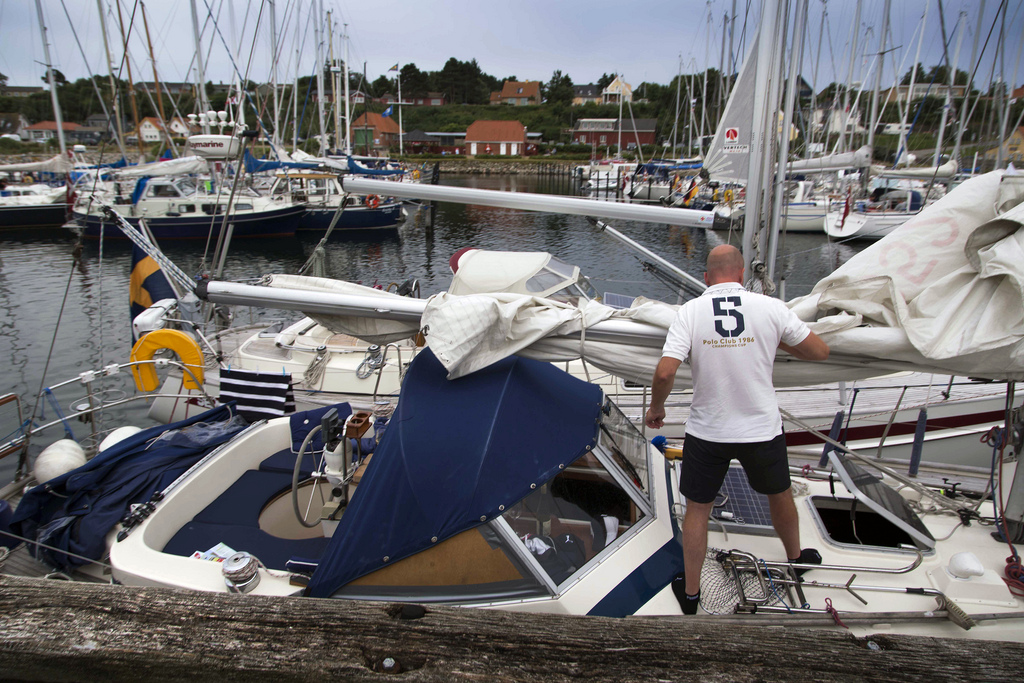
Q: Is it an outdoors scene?
A: Yes, it is outdoors.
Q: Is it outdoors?
A: Yes, it is outdoors.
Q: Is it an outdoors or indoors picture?
A: It is outdoors.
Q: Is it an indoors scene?
A: No, it is outdoors.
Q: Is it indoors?
A: No, it is outdoors.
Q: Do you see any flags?
A: Yes, there is a flag.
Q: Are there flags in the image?
A: Yes, there is a flag.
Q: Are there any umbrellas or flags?
A: Yes, there is a flag.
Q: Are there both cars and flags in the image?
A: No, there is a flag but no cars.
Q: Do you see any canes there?
A: No, there are no canes.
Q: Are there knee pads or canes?
A: No, there are no canes or knee pads.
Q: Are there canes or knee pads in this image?
A: No, there are no canes or knee pads.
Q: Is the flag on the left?
A: Yes, the flag is on the left of the image.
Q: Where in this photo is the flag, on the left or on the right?
A: The flag is on the left of the image.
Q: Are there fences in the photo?
A: No, there are no fences.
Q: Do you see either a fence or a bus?
A: No, there are no fences or buses.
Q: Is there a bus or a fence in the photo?
A: No, there are no fences or buses.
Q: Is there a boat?
A: Yes, there is a boat.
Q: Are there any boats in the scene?
A: Yes, there is a boat.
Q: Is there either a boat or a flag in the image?
A: Yes, there is a boat.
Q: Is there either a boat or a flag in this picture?
A: Yes, there is a boat.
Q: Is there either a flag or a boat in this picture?
A: Yes, there is a boat.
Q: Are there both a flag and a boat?
A: Yes, there are both a boat and a flag.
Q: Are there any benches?
A: No, there are no benches.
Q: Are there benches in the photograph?
A: No, there are no benches.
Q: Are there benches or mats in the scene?
A: No, there are no benches or mats.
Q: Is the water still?
A: Yes, the water is still.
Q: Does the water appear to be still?
A: Yes, the water is still.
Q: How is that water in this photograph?
A: The water is still.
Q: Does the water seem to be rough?
A: No, the water is still.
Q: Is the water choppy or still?
A: The water is still.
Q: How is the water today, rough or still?
A: The water is still.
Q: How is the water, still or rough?
A: The water is still.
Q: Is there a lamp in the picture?
A: No, there are no lamps.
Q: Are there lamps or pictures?
A: No, there are no lamps or pictures.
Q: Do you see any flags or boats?
A: Yes, there is a boat.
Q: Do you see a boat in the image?
A: Yes, there is a boat.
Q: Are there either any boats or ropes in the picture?
A: Yes, there is a boat.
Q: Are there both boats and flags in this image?
A: Yes, there are both a boat and a flag.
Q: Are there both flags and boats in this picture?
A: Yes, there are both a boat and a flag.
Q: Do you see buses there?
A: No, there are no buses.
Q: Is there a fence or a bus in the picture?
A: No, there are no buses or fences.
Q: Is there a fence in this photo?
A: No, there are no fences.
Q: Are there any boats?
A: Yes, there is a boat.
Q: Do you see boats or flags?
A: Yes, there is a boat.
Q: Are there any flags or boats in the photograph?
A: Yes, there is a boat.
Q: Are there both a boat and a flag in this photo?
A: Yes, there are both a boat and a flag.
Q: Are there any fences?
A: No, there are no fences.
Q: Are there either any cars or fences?
A: No, there are no fences or cars.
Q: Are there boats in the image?
A: Yes, there is a boat.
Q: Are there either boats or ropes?
A: Yes, there is a boat.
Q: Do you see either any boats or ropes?
A: Yes, there is a boat.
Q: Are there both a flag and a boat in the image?
A: Yes, there are both a boat and a flag.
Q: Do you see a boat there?
A: Yes, there is a boat.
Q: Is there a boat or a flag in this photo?
A: Yes, there is a boat.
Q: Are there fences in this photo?
A: No, there are no fences.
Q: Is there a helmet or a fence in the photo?
A: No, there are no fences or helmets.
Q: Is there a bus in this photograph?
A: No, there are no buses.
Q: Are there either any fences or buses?
A: No, there are no buses or fences.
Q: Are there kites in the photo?
A: No, there are no kites.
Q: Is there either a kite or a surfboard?
A: No, there are no kites or surfboards.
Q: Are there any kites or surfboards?
A: No, there are no kites or surfboards.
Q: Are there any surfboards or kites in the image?
A: No, there are no kites or surfboards.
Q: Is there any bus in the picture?
A: No, there are no buses.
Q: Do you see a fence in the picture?
A: No, there are no fences.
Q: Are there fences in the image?
A: No, there are no fences.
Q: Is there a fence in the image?
A: No, there are no fences.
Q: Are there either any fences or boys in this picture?
A: No, there are no fences or boys.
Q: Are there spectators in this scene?
A: No, there are no spectators.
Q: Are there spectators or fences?
A: No, there are no spectators or fences.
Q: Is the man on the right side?
A: Yes, the man is on the right of the image.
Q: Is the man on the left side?
A: No, the man is on the right of the image.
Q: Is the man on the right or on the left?
A: The man is on the right of the image.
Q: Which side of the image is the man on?
A: The man is on the right of the image.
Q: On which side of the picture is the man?
A: The man is on the right of the image.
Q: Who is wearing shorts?
A: The man is wearing shorts.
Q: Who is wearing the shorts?
A: The man is wearing shorts.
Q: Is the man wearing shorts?
A: Yes, the man is wearing shorts.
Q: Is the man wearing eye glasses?
A: No, the man is wearing shorts.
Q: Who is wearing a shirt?
A: The man is wearing a shirt.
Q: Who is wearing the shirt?
A: The man is wearing a shirt.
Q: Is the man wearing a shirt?
A: Yes, the man is wearing a shirt.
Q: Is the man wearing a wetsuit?
A: No, the man is wearing a shirt.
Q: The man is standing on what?
A: The man is standing on the boat.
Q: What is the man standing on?
A: The man is standing on the boat.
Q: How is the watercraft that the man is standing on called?
A: The watercraft is a boat.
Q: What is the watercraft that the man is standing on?
A: The watercraft is a boat.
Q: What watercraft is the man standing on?
A: The man is standing on the boat.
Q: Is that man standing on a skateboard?
A: No, the man is standing on the boat.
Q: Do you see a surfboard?
A: No, there are no surfboards.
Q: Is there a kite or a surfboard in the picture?
A: No, there are no surfboards or kites.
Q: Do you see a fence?
A: No, there are no fences.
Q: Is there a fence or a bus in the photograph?
A: No, there are no fences or buses.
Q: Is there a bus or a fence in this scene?
A: No, there are no fences or buses.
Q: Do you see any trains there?
A: No, there are no trains.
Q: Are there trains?
A: No, there are no trains.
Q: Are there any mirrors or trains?
A: No, there are no trains or mirrors.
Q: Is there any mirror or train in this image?
A: No, there are no trains or mirrors.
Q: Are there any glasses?
A: No, there are no glasses.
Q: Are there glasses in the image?
A: No, there are no glasses.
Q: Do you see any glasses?
A: No, there are no glasses.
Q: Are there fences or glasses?
A: No, there are no glasses or fences.